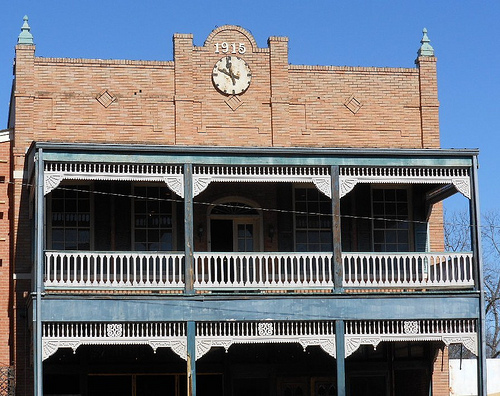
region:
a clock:
[119, 6, 346, 198]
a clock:
[136, 65, 431, 160]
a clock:
[181, 42, 428, 222]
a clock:
[148, 60, 360, 131]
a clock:
[139, 17, 259, 86]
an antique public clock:
[205, 54, 254, 99]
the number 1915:
[208, 42, 250, 54]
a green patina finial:
[14, 14, 34, 45]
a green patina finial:
[413, 24, 434, 56]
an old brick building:
[13, 20, 474, 394]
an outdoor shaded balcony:
[22, 146, 482, 304]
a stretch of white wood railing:
[40, 247, 186, 289]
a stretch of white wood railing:
[192, 250, 332, 293]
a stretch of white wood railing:
[340, 250, 474, 290]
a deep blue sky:
[0, 1, 497, 285]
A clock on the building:
[213, 62, 263, 97]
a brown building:
[292, 68, 429, 140]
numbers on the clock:
[234, 58, 254, 91]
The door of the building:
[227, 222, 263, 247]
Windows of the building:
[373, 197, 412, 247]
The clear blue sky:
[308, 11, 395, 54]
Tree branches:
[481, 218, 497, 258]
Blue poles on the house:
[176, 193, 213, 295]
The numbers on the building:
[215, 40, 257, 55]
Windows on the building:
[133, 211, 173, 243]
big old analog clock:
[203, 51, 256, 98]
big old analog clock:
[209, 40, 264, 119]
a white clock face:
[210, 53, 255, 97]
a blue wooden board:
[181, 318, 206, 394]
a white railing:
[43, 244, 483, 289]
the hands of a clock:
[215, 56, 244, 83]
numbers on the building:
[211, 38, 250, 55]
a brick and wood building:
[1, 11, 491, 394]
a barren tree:
[444, 206, 498, 361]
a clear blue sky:
[1, 0, 499, 357]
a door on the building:
[231, 214, 265, 295]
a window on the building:
[131, 180, 181, 275]